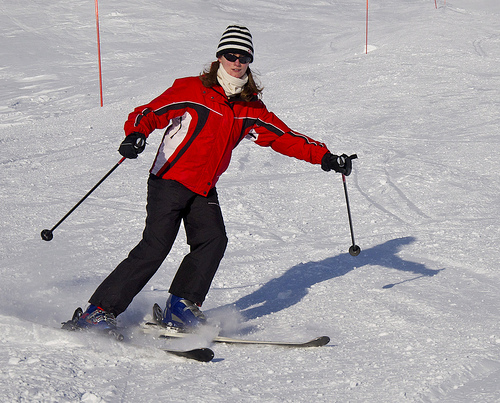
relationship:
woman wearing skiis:
[73, 22, 354, 344] [131, 323, 331, 346]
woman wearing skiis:
[73, 22, 354, 344] [166, 345, 216, 364]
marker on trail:
[434, 0, 437, 9] [0, 0, 498, 402]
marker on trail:
[363, 0, 370, 53] [0, 0, 498, 402]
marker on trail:
[93, 0, 103, 106] [0, 0, 498, 402]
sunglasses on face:
[220, 53, 252, 62] [220, 47, 251, 82]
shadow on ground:
[226, 202, 434, 311] [1, 0, 498, 399]